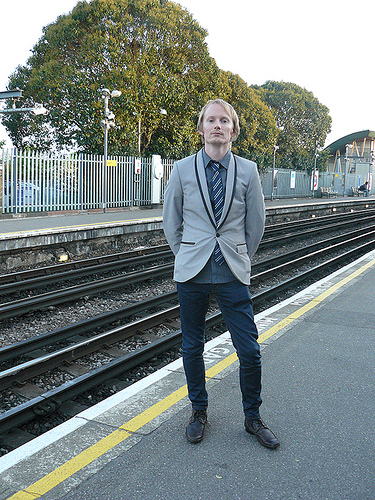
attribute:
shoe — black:
[242, 415, 280, 451]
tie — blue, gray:
[198, 148, 238, 251]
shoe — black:
[241, 411, 281, 449]